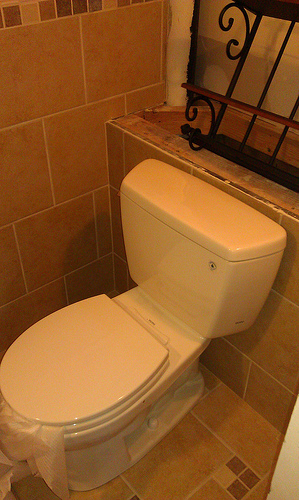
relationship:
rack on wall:
[203, 26, 284, 157] [156, 4, 293, 185]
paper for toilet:
[0, 414, 90, 478] [46, 222, 198, 442]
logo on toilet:
[189, 244, 235, 281] [46, 222, 198, 442]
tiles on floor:
[178, 410, 279, 493] [108, 440, 248, 498]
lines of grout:
[232, 345, 258, 381] [228, 343, 296, 407]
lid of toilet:
[75, 302, 185, 407] [46, 222, 198, 442]